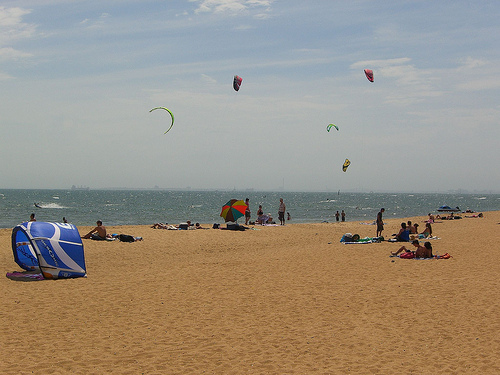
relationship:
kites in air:
[243, 36, 383, 181] [43, 29, 224, 72]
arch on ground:
[6, 221, 87, 281] [65, 287, 271, 353]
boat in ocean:
[428, 200, 460, 217] [1, 187, 498, 228]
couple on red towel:
[388, 240, 435, 260] [396, 250, 451, 260]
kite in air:
[338, 156, 352, 176] [119, 27, 181, 65]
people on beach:
[204, 187, 340, 262] [53, 133, 460, 340]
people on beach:
[277, 196, 287, 224] [2, 211, 499, 373]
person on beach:
[416, 222, 436, 244] [2, 211, 499, 373]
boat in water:
[436, 204, 460, 212] [1, 190, 498, 230]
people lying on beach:
[277, 196, 287, 224] [24, 22, 496, 357]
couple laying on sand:
[389, 239, 433, 261] [204, 270, 315, 320]